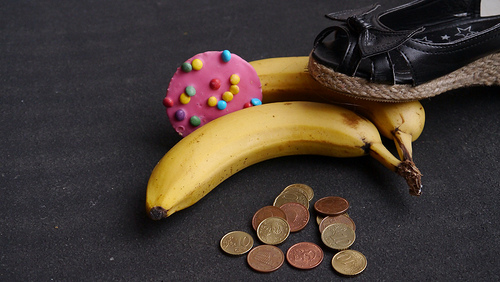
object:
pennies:
[219, 183, 367, 276]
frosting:
[161, 50, 263, 140]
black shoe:
[306, 0, 500, 102]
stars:
[415, 25, 478, 42]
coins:
[215, 173, 383, 280]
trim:
[299, 53, 500, 103]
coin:
[256, 216, 291, 246]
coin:
[281, 183, 314, 202]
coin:
[331, 250, 368, 276]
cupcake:
[161, 49, 264, 138]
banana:
[247, 56, 425, 162]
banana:
[144, 101, 423, 221]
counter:
[0, 0, 500, 282]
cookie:
[162, 49, 263, 139]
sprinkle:
[208, 78, 221, 91]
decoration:
[221, 49, 232, 62]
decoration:
[250, 98, 262, 106]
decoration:
[181, 62, 193, 72]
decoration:
[185, 86, 196, 97]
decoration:
[175, 109, 186, 121]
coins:
[312, 196, 359, 251]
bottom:
[148, 206, 168, 221]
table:
[0, 0, 500, 282]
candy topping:
[209, 79, 221, 90]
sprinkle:
[185, 85, 196, 96]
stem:
[366, 128, 424, 197]